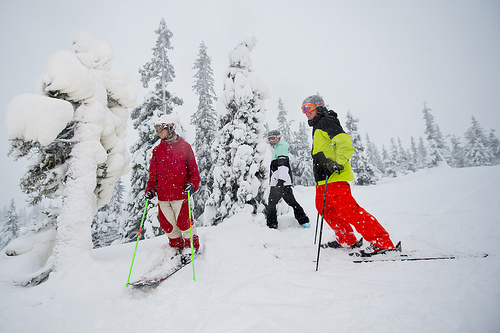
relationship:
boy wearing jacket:
[137, 110, 206, 261] [141, 134, 203, 199]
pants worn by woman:
[311, 182, 394, 249] [282, 92, 398, 257]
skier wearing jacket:
[300, 95, 394, 258] [285, 107, 394, 182]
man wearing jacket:
[265, 130, 310, 228] [269, 134, 293, 187]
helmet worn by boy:
[151, 112, 178, 142] [143, 117, 201, 265]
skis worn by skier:
[123, 240, 215, 292] [289, 90, 406, 258]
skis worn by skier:
[294, 235, 496, 272] [252, 126, 312, 233]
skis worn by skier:
[294, 235, 496, 272] [125, 111, 212, 261]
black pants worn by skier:
[261, 183, 311, 228] [300, 95, 394, 258]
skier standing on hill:
[302, 97, 394, 258] [383, 164, 493, 331]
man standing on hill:
[267, 130, 310, 228] [383, 164, 493, 331]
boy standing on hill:
[143, 117, 201, 265] [383, 164, 493, 331]